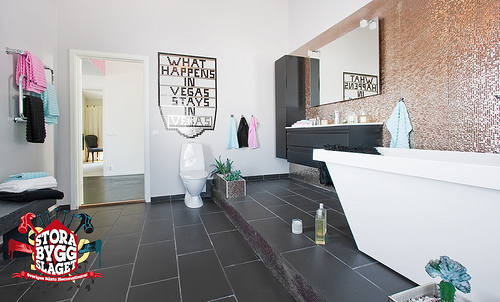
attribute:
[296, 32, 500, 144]
wall — brown, hanging up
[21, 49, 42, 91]
towel — pink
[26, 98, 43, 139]
towel — black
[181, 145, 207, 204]
toilet — porcelain, white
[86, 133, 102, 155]
chair — black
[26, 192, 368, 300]
floor — tile, black, brick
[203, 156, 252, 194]
plants — green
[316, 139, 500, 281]
bathtub — white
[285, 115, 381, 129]
counter — white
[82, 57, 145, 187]
door — white